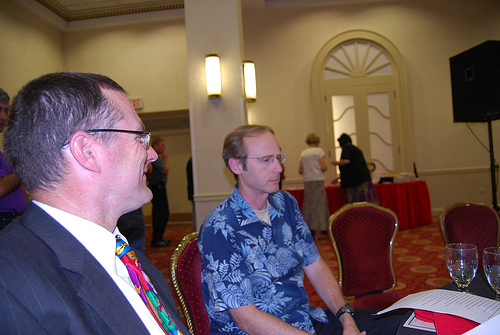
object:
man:
[0, 70, 197, 335]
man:
[195, 122, 403, 335]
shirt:
[196, 183, 329, 335]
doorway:
[304, 24, 416, 182]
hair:
[2, 69, 130, 193]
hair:
[221, 123, 275, 181]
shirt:
[31, 201, 178, 335]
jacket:
[0, 202, 189, 335]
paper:
[401, 312, 437, 333]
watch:
[335, 303, 357, 322]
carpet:
[124, 212, 499, 334]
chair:
[437, 198, 499, 275]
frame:
[169, 231, 207, 335]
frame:
[326, 202, 400, 297]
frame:
[437, 199, 500, 275]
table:
[280, 175, 432, 232]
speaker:
[447, 36, 498, 213]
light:
[243, 58, 257, 105]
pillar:
[180, 0, 255, 229]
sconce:
[201, 53, 222, 104]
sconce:
[241, 59, 256, 104]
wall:
[184, 0, 249, 232]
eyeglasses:
[231, 153, 287, 164]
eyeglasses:
[60, 125, 154, 150]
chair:
[169, 222, 211, 334]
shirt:
[299, 146, 326, 183]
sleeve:
[318, 149, 326, 159]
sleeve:
[298, 150, 305, 163]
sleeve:
[196, 220, 245, 323]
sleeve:
[285, 193, 320, 268]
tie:
[113, 230, 183, 335]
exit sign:
[129, 97, 144, 109]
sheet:
[372, 288, 500, 324]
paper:
[372, 287, 500, 325]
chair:
[327, 199, 417, 310]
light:
[202, 52, 221, 100]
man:
[144, 138, 171, 247]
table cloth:
[282, 179, 430, 230]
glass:
[444, 242, 479, 294]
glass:
[480, 242, 500, 299]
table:
[318, 264, 500, 335]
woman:
[330, 132, 378, 208]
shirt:
[338, 146, 371, 188]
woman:
[296, 133, 330, 235]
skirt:
[300, 180, 329, 232]